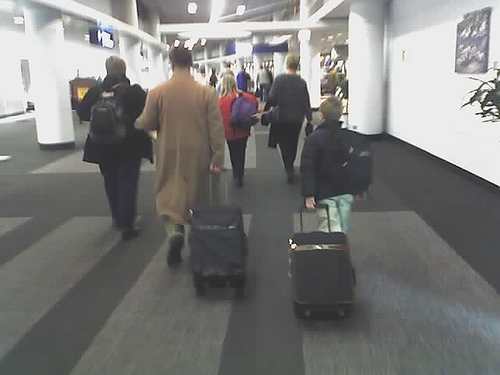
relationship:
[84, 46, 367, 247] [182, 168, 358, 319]
people have suitcases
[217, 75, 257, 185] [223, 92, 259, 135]
woman has backpack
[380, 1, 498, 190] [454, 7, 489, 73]
wall has a picture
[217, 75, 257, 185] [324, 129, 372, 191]
woman has backpack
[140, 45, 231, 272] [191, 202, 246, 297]
man has a suitcase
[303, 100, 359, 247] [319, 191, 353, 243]
boy has pants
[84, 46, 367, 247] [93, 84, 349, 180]
people have backs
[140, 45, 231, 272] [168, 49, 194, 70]
man has a head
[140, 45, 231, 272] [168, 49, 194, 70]
man has head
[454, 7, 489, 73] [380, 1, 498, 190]
picture on wall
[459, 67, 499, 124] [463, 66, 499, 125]
leaves has leaves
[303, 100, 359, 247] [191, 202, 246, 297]
boy has suitcase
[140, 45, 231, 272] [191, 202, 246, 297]
man has suitcase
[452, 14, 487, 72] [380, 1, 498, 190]
picture on wall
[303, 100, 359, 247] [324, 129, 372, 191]
boy has backpack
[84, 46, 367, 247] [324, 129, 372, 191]
people have a backpack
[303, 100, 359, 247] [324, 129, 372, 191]
boy has a backpack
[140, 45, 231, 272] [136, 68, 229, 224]
man wearing coat